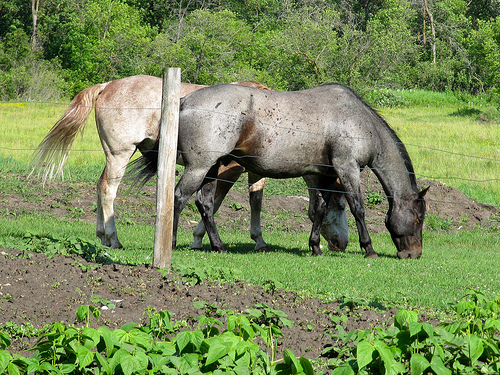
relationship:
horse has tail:
[28, 74, 349, 250] [27, 82, 110, 188]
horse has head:
[126, 82, 428, 259] [384, 185, 432, 260]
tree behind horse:
[157, 11, 237, 88] [126, 82, 428, 259]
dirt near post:
[271, 167, 495, 231] [151, 67, 181, 267]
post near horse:
[151, 67, 181, 267] [126, 82, 428, 259]